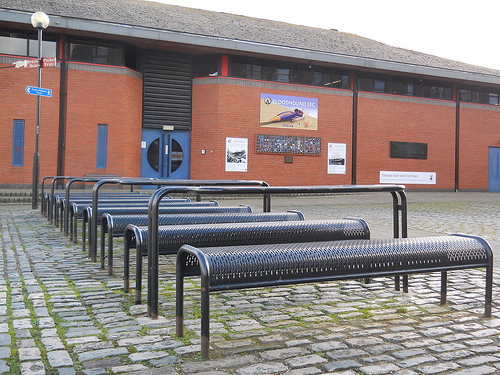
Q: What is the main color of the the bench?
A: Brown.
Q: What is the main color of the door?
A: Blue.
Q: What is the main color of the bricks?
A: Gray.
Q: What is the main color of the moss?
A: Green.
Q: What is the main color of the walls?
A: Red.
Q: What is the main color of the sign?
A: Blue.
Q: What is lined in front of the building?
A: Benches.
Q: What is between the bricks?
A: Grass.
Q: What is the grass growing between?
A: Bricks.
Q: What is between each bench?
A: Railing.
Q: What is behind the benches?
A: Building.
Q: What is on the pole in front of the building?
A: Light.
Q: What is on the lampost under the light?
A: Signs.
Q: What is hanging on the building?
A: Advertisement.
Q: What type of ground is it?
A: Stone.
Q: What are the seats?
A: Benches.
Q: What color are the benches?
A: Black.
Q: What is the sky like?
A: Overcast.